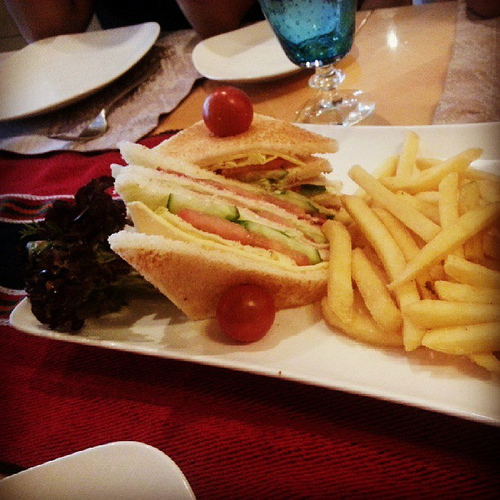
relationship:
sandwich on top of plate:
[110, 84, 339, 346] [7, 119, 499, 427]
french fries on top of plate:
[319, 129, 499, 375] [7, 119, 499, 427]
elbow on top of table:
[189, 15, 240, 39] [148, 0, 459, 129]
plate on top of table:
[1, 439, 201, 500] [148, 0, 459, 129]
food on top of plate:
[26, 85, 499, 373] [7, 119, 499, 427]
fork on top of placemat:
[46, 61, 161, 142] [1, 27, 205, 158]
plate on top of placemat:
[1, 21, 160, 126] [1, 27, 205, 158]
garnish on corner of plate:
[21, 174, 161, 334] [7, 119, 499, 427]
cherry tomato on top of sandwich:
[203, 84, 254, 138] [110, 84, 339, 346]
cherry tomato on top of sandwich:
[218, 281, 276, 345] [110, 84, 339, 346]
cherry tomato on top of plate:
[203, 84, 254, 138] [7, 119, 499, 427]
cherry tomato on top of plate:
[218, 281, 276, 345] [7, 119, 499, 427]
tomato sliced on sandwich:
[183, 206, 307, 266] [110, 84, 339, 346]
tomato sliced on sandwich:
[221, 156, 297, 176] [110, 84, 339, 346]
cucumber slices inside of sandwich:
[164, 192, 321, 265] [110, 84, 339, 346]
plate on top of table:
[192, 16, 312, 83] [148, 0, 459, 129]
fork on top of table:
[46, 61, 161, 142] [148, 0, 459, 129]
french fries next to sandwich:
[319, 129, 499, 375] [110, 84, 339, 346]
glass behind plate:
[261, 0, 375, 127] [192, 16, 312, 83]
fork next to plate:
[46, 61, 161, 142] [1, 21, 160, 126]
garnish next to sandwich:
[21, 174, 161, 334] [110, 84, 339, 346]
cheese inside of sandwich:
[127, 199, 329, 271] [110, 84, 339, 346]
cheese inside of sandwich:
[204, 150, 306, 170] [110, 84, 339, 346]